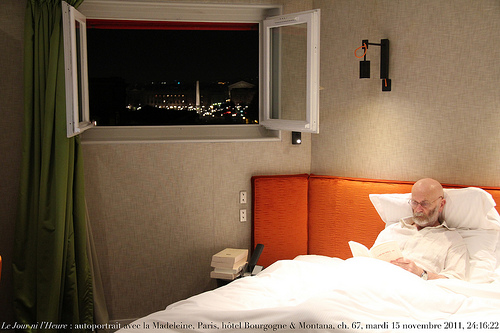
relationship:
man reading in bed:
[374, 177, 468, 278] [115, 175, 499, 329]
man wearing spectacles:
[374, 177, 468, 278] [410, 201, 442, 209]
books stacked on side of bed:
[209, 246, 250, 280] [115, 175, 499, 329]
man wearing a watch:
[374, 177, 468, 278] [421, 269, 430, 278]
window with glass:
[63, 0, 322, 140] [271, 26, 306, 121]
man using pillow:
[374, 177, 468, 278] [368, 186, 499, 228]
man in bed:
[374, 177, 468, 278] [115, 175, 499, 329]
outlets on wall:
[241, 189, 248, 228] [1, 2, 497, 321]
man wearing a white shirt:
[374, 177, 468, 278] [374, 220, 467, 273]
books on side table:
[209, 246, 250, 280] [215, 266, 262, 290]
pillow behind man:
[368, 186, 499, 228] [374, 177, 468, 278]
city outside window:
[123, 72, 256, 121] [63, 0, 322, 140]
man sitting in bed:
[374, 177, 468, 278] [115, 175, 499, 329]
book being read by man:
[345, 240, 396, 263] [374, 177, 468, 278]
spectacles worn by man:
[410, 201, 442, 209] [374, 177, 468, 278]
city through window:
[123, 72, 256, 121] [63, 0, 322, 140]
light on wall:
[354, 39, 392, 92] [1, 2, 497, 321]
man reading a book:
[374, 177, 468, 278] [345, 240, 396, 263]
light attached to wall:
[354, 39, 392, 92] [1, 2, 497, 321]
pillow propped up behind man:
[368, 186, 499, 228] [374, 177, 468, 278]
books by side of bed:
[209, 246, 250, 280] [115, 175, 499, 329]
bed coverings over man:
[117, 256, 497, 329] [374, 177, 468, 278]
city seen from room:
[123, 72, 256, 121] [4, 6, 499, 332]